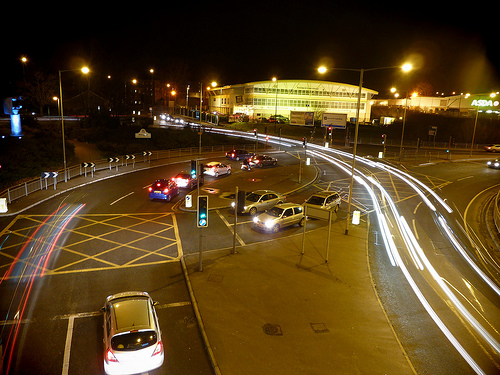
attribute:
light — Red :
[154, 180, 161, 188]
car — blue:
[301, 190, 341, 217]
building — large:
[202, 72, 380, 134]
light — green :
[200, 214, 209, 224]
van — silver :
[306, 183, 351, 228]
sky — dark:
[2, 3, 498, 151]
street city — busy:
[2, 69, 495, 371]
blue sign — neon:
[6, 103, 30, 154]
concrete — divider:
[250, 261, 365, 358]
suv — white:
[96, 288, 170, 373]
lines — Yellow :
[5, 204, 186, 275]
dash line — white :
[410, 174, 475, 239]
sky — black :
[4, 5, 499, 104]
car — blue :
[142, 174, 179, 208]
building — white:
[203, 75, 380, 125]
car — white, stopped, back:
[96, 283, 166, 373]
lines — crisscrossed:
[2, 140, 457, 288]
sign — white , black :
[40, 170, 60, 182]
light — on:
[315, 62, 328, 76]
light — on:
[397, 60, 415, 75]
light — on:
[269, 75, 279, 82]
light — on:
[209, 79, 218, 89]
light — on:
[203, 84, 211, 90]